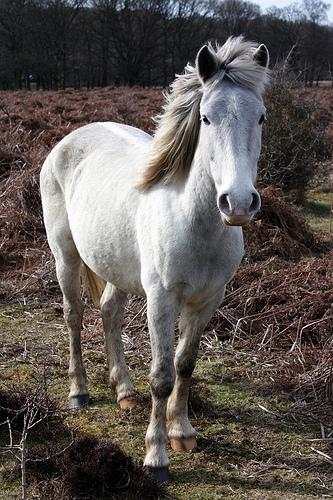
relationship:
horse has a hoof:
[37, 36, 268, 477] [169, 438, 198, 455]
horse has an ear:
[37, 36, 268, 477] [197, 47, 219, 80]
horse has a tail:
[37, 36, 268, 477] [84, 266, 110, 306]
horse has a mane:
[37, 36, 268, 477] [139, 35, 274, 192]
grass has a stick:
[1, 79, 332, 498] [1, 361, 74, 499]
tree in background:
[108, 3, 167, 84] [1, 0, 332, 137]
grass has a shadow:
[1, 79, 332, 498] [195, 437, 332, 474]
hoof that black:
[169, 438, 198, 455] [146, 467, 169, 486]